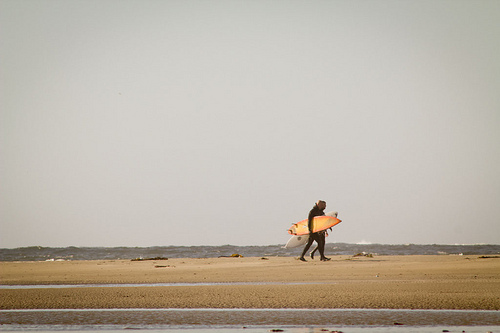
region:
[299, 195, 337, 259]
these are two men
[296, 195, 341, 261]
the men are walking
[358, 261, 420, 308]
this is the beach sabd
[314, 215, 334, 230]
this is a surf board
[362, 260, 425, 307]
the sand is brown in color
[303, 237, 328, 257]
these are the legs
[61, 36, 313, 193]
this is the sky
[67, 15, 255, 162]
the sky is grey in color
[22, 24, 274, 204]
the sky is clear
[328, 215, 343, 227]
this is the tip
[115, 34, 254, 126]
this is the sky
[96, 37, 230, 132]
the sky is big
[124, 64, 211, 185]
the sky has clouds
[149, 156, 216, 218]
the clouds are white in color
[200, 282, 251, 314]
this is the ground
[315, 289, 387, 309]
the ground is sandy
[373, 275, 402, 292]
the sand is brown in color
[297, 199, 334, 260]
these are two people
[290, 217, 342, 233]
these are two surfboards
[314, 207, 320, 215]
the cloth is black in color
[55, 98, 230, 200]
the sky is overcast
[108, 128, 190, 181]
the sky is overcast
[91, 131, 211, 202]
the sky is overcast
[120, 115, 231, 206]
the sky is overcast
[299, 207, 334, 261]
the wet suit is black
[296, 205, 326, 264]
the wet suit is black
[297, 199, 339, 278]
the wet suit is black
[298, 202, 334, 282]
the wet suit is black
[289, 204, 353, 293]
the wet suit is black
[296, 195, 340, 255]
these are two men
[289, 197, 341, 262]
the men are walking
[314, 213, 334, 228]
this is a surfboard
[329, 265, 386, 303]
this is the beach sand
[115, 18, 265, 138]
the sky is clear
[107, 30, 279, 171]
the sky is grey in color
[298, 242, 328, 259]
these are the legs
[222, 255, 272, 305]
the sand is brown in color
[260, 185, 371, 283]
the people carrying surfboards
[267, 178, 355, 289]
the people carrying surfboards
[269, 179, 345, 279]
the people carrying surfboards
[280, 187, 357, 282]
the people carrying surfboards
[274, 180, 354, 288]
the people carrying surfboards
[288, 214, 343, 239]
the surfboard is orange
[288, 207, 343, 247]
the surfboard is orange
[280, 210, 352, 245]
the surfboard is orange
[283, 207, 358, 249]
the surfboard is orange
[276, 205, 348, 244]
the surfboard is orange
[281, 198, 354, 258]
man carrying a surfboard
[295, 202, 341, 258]
man wearing a black wet suit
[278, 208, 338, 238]
man holding a orange surfboard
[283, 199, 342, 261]
two people carrying surfboards